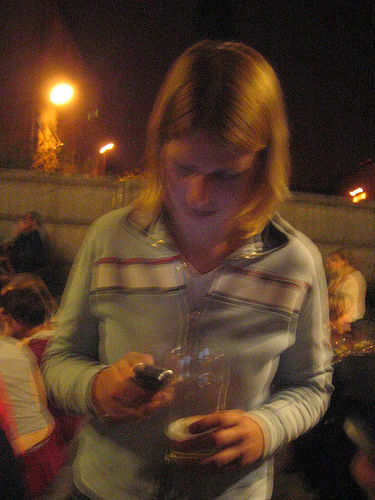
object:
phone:
[134, 359, 173, 394]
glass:
[162, 343, 230, 476]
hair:
[139, 36, 295, 241]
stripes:
[88, 251, 186, 271]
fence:
[0, 168, 374, 290]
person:
[325, 249, 370, 339]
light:
[45, 76, 82, 112]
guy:
[8, 218, 47, 277]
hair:
[3, 274, 48, 327]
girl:
[40, 40, 335, 499]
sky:
[1, 0, 372, 204]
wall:
[1, 169, 374, 298]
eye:
[211, 167, 245, 184]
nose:
[184, 175, 216, 206]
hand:
[88, 352, 174, 425]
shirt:
[325, 269, 366, 327]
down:
[10, 405, 245, 499]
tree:
[30, 111, 66, 172]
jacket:
[43, 205, 334, 499]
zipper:
[183, 303, 199, 353]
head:
[144, 38, 287, 241]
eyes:
[172, 165, 195, 177]